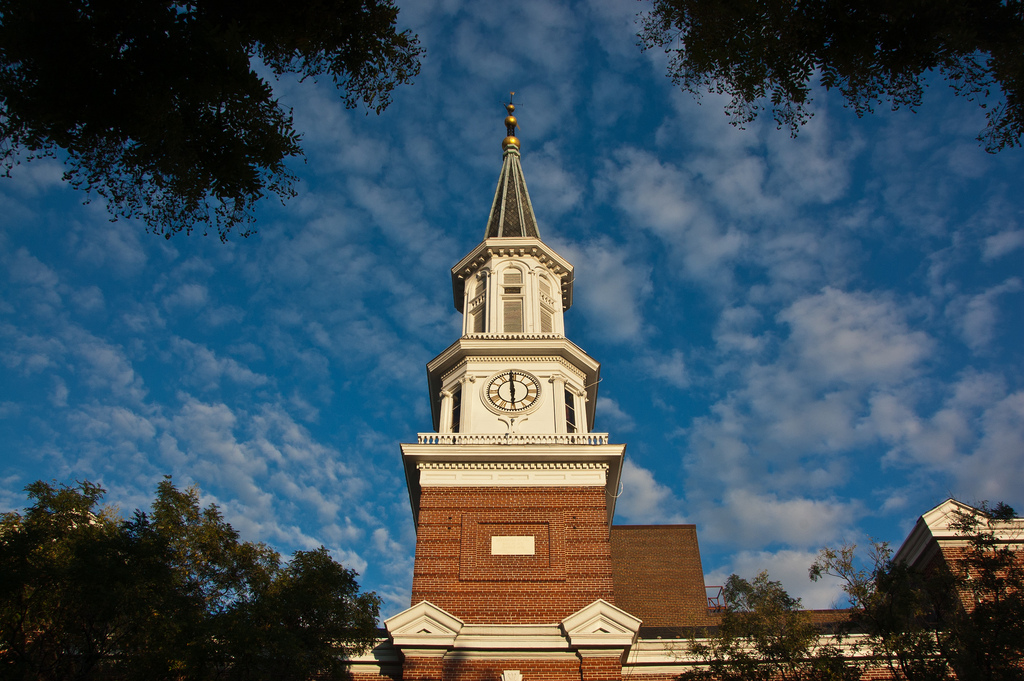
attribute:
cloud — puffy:
[65, 170, 415, 389]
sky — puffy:
[131, 129, 475, 374]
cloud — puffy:
[125, 118, 560, 397]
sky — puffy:
[101, 90, 419, 298]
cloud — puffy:
[62, 178, 393, 460]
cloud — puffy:
[123, 77, 463, 216]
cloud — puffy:
[203, 142, 649, 417]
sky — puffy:
[199, 58, 940, 400]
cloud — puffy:
[631, 252, 822, 467]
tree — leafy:
[93, 60, 199, 166]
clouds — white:
[24, 114, 606, 385]